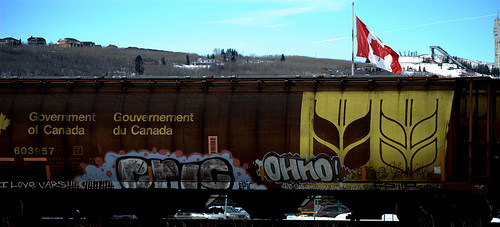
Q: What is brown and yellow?
A: The train.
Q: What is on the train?
A: White and black graffiti.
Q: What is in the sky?
A: Clouds.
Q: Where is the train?
A: Tracks.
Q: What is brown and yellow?
A: Box car.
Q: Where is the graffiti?
A: On the side of box car.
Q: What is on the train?
A: Graffiti.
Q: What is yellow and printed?
A: Logo.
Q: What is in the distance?
A: Hillside.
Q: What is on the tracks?
A: Train.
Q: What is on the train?
A: Paint.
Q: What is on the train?
A: Illustration.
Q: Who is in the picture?
A: There are no people in the image.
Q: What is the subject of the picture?
A: A train.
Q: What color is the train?
A: Brown and yellow.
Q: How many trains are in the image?
A: One.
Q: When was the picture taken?
A: During the day.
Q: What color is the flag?
A: White and red.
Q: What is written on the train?
A: Gouvernement du Canada.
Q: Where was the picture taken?
A: Train yard.